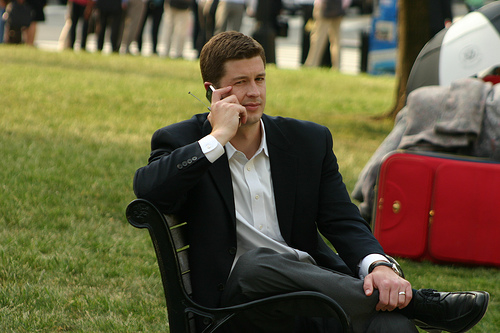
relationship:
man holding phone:
[130, 25, 494, 332] [185, 85, 247, 125]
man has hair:
[130, 25, 494, 332] [193, 28, 272, 89]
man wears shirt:
[130, 25, 494, 332] [197, 110, 317, 285]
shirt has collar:
[197, 110, 317, 285] [218, 118, 272, 166]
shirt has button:
[197, 110, 317, 285] [246, 166, 257, 175]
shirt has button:
[197, 110, 317, 285] [253, 192, 261, 202]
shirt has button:
[197, 110, 317, 285] [255, 220, 266, 232]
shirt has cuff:
[197, 110, 317, 285] [194, 133, 229, 165]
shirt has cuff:
[197, 110, 317, 285] [354, 249, 392, 281]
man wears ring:
[130, 25, 494, 332] [398, 288, 407, 300]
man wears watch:
[130, 25, 494, 332] [368, 260, 403, 278]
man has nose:
[130, 25, 494, 332] [244, 80, 263, 101]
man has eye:
[130, 25, 494, 332] [254, 73, 266, 85]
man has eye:
[130, 25, 494, 332] [230, 74, 249, 89]